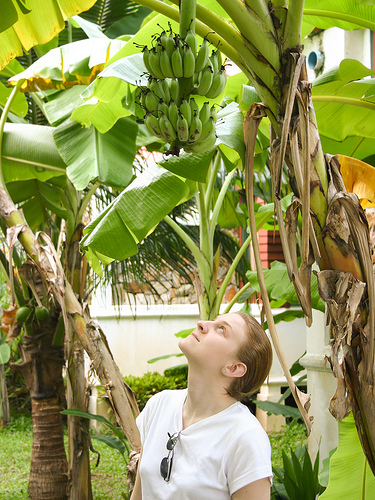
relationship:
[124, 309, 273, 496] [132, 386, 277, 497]
girl wearing shirt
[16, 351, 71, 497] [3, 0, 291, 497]
brown base of banana tree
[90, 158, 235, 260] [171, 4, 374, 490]
leaf of a banana tree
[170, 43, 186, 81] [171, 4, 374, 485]
bananas not ripe yet on a banana tree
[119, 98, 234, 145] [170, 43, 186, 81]
bunch of a bananas not ripe yet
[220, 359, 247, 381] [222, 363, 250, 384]
ear of a person looking up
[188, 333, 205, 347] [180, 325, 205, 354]
mouth looking up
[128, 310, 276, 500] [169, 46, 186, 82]
person looking at banana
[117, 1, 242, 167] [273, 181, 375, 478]
bananas hanging hanging from brown banana tree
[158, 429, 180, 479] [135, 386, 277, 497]
dark sunglasses hung in shirt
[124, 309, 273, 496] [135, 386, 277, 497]
girl with blonde hair in white shirt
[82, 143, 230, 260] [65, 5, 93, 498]
leaf of banana banana tree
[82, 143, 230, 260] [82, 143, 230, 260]
leaf of banana leaf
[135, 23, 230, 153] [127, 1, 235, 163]
bunch of bananas not ripe yet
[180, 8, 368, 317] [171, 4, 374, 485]
red building behind banana tree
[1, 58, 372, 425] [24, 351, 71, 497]
brown dead leaves of banana brown base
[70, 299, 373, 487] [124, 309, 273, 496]
white structure behind a girl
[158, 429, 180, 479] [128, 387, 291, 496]
dark sunglasses hanging from t-shirt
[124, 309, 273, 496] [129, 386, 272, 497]
girl wearing t-shirt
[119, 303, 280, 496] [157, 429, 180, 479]
girl looking up with hanging from t-shirt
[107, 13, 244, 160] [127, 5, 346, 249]
banana hanging from tree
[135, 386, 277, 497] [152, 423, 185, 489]
shirt with sunglasses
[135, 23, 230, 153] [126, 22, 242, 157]
bunch of bananas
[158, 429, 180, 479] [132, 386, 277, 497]
dark sunglasses on front of shirt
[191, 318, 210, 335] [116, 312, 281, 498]
nose of a person of a person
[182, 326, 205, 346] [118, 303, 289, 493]
mouth of a person looking